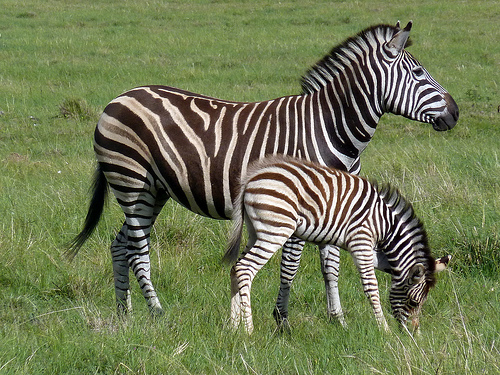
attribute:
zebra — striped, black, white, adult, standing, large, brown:
[51, 18, 459, 319]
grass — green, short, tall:
[2, 1, 499, 373]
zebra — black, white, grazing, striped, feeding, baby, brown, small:
[210, 152, 437, 343]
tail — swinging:
[209, 184, 248, 274]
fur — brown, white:
[211, 153, 436, 337]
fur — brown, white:
[58, 21, 459, 323]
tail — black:
[57, 162, 114, 268]